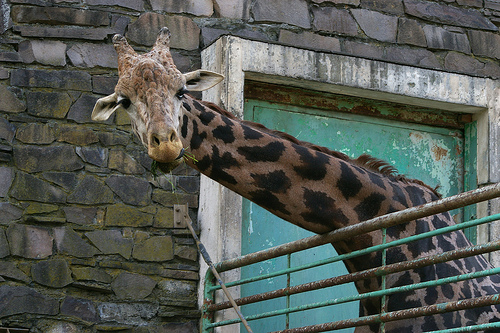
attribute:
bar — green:
[288, 222, 445, 289]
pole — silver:
[180, 206, 251, 331]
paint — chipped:
[258, 221, 262, 225]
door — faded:
[244, 91, 472, 331]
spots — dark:
[276, 155, 400, 218]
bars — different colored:
[216, 257, 451, 330]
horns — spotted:
[102, 21, 194, 66]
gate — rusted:
[230, 187, 497, 319]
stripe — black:
[291, 142, 331, 179]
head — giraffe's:
[95, 29, 228, 166]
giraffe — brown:
[77, 30, 496, 328]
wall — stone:
[3, 0, 498, 332]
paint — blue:
[236, 93, 479, 328]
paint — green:
[378, 269, 498, 285]